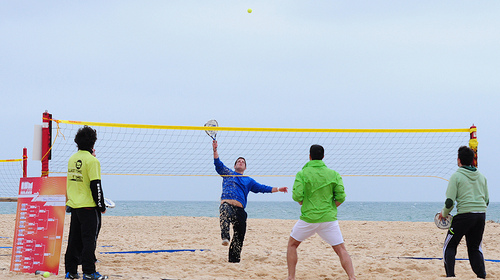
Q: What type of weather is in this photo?
A: It is cloudy.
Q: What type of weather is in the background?
A: It is cloudy.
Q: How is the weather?
A: It is cloudy.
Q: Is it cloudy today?
A: Yes, it is cloudy.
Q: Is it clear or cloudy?
A: It is cloudy.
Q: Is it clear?
A: No, it is cloudy.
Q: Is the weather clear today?
A: No, it is cloudy.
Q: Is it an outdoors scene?
A: Yes, it is outdoors.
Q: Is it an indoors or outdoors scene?
A: It is outdoors.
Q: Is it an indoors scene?
A: No, it is outdoors.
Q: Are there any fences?
A: No, there are no fences.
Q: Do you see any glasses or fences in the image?
A: No, there are no fences or glasses.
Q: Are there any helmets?
A: No, there are no helmets.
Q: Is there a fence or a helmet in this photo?
A: No, there are no helmets or fences.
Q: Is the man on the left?
A: Yes, the man is on the left of the image.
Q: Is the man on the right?
A: No, the man is on the left of the image.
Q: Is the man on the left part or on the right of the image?
A: The man is on the left of the image.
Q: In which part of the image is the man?
A: The man is on the left of the image.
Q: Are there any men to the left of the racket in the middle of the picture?
A: Yes, there is a man to the left of the tennis racket.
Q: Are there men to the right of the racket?
A: No, the man is to the left of the racket.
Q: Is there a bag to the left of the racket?
A: No, there is a man to the left of the racket.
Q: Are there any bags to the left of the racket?
A: No, there is a man to the left of the racket.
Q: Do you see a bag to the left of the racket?
A: No, there is a man to the left of the racket.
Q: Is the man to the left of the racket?
A: Yes, the man is to the left of the racket.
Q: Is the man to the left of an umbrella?
A: No, the man is to the left of the racket.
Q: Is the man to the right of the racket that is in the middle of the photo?
A: No, the man is to the left of the tennis racket.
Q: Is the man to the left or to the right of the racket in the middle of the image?
A: The man is to the left of the tennis racket.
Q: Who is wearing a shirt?
A: The man is wearing a shirt.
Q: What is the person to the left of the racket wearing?
A: The man is wearing a shirt.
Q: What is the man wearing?
A: The man is wearing a shirt.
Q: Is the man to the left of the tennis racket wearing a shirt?
A: Yes, the man is wearing a shirt.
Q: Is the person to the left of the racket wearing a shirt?
A: Yes, the man is wearing a shirt.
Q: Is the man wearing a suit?
A: No, the man is wearing a shirt.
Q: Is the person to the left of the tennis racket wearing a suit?
A: No, the man is wearing a shirt.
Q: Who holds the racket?
A: The man holds the racket.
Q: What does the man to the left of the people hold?
A: The man holds the racket.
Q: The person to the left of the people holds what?
A: The man holds the racket.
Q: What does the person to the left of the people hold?
A: The man holds the racket.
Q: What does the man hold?
A: The man holds the racket.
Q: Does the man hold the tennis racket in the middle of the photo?
A: Yes, the man holds the tennis racket.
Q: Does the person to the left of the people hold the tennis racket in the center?
A: Yes, the man holds the tennis racket.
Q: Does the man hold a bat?
A: No, the man holds the tennis racket.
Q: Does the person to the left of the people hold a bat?
A: No, the man holds the tennis racket.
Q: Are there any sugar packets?
A: No, there are no sugar packets.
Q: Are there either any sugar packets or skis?
A: No, there are no sugar packets or skis.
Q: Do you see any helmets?
A: No, there are no helmets.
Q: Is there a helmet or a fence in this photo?
A: No, there are no helmets or fences.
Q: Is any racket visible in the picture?
A: Yes, there is a racket.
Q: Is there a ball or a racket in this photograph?
A: Yes, there is a racket.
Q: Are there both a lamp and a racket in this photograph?
A: No, there is a racket but no lamps.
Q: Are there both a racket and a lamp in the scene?
A: No, there is a racket but no lamps.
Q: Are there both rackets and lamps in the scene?
A: No, there is a racket but no lamps.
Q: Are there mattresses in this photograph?
A: No, there are no mattresses.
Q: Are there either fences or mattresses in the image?
A: No, there are no mattresses or fences.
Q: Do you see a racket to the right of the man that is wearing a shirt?
A: Yes, there is a racket to the right of the man.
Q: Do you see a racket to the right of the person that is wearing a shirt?
A: Yes, there is a racket to the right of the man.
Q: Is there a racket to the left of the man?
A: No, the racket is to the right of the man.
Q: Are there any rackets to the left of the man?
A: No, the racket is to the right of the man.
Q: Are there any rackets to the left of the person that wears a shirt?
A: No, the racket is to the right of the man.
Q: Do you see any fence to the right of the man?
A: No, there is a racket to the right of the man.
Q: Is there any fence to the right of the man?
A: No, there is a racket to the right of the man.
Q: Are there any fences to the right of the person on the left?
A: No, there is a racket to the right of the man.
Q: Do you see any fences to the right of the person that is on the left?
A: No, there is a racket to the right of the man.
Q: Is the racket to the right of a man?
A: Yes, the racket is to the right of a man.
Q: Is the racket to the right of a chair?
A: No, the racket is to the right of a man.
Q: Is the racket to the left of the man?
A: No, the racket is to the right of the man.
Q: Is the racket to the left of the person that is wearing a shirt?
A: No, the racket is to the right of the man.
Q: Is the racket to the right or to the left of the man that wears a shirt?
A: The racket is to the right of the man.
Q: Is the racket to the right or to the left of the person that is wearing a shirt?
A: The racket is to the right of the man.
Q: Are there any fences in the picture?
A: No, there are no fences.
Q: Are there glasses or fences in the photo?
A: No, there are no fences or glasses.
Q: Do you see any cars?
A: No, there are no cars.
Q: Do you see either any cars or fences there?
A: No, there are no cars or fences.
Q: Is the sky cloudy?
A: Yes, the sky is cloudy.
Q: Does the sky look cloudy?
A: Yes, the sky is cloudy.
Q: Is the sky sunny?
A: No, the sky is cloudy.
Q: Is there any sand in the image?
A: Yes, there is sand.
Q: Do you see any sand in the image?
A: Yes, there is sand.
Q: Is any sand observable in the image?
A: Yes, there is sand.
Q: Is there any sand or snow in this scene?
A: Yes, there is sand.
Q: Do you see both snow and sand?
A: No, there is sand but no snow.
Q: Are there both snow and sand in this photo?
A: No, there is sand but no snow.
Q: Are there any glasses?
A: No, there are no glasses.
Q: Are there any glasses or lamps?
A: No, there are no glasses or lamps.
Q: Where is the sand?
A: The sand is on the beach.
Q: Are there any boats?
A: No, there are no boats.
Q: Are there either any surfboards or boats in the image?
A: No, there are no boats or surfboards.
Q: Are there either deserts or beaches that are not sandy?
A: No, there is a beach but it is sandy.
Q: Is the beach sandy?
A: Yes, the beach is sandy.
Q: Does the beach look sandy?
A: Yes, the beach is sandy.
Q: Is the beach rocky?
A: No, the beach is sandy.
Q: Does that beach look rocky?
A: No, the beach is sandy.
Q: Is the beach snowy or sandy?
A: The beach is sandy.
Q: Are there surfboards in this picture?
A: No, there are no surfboards.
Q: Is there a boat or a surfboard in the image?
A: No, there are no surfboards or boats.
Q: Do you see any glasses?
A: No, there are no glasses.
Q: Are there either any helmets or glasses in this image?
A: No, there are no glasses or helmets.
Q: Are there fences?
A: No, there are no fences.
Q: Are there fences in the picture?
A: No, there are no fences.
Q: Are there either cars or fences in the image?
A: No, there are no fences or cars.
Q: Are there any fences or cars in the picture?
A: No, there are no fences or cars.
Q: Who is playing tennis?
A: The people are playing tennis.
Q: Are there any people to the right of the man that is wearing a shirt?
A: Yes, there are people to the right of the man.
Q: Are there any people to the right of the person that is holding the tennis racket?
A: Yes, there are people to the right of the man.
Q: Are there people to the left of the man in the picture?
A: No, the people are to the right of the man.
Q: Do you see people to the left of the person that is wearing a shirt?
A: No, the people are to the right of the man.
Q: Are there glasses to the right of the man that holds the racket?
A: No, there are people to the right of the man.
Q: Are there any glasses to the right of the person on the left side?
A: No, there are people to the right of the man.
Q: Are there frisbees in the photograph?
A: No, there are no frisbees.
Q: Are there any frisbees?
A: No, there are no frisbees.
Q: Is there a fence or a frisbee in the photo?
A: No, there are no frisbees or fences.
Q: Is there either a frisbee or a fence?
A: No, there are no frisbees or fences.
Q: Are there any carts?
A: No, there are no carts.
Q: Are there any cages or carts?
A: No, there are no carts or cages.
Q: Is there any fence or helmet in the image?
A: No, there are no fences or helmets.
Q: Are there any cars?
A: No, there are no cars.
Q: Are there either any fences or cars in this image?
A: No, there are no cars or fences.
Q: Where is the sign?
A: The sign is in the sand.